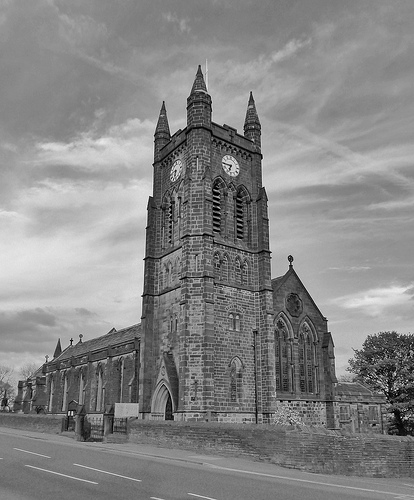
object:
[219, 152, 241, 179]
clock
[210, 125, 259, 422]
wall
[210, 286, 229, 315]
bricks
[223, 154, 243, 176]
6:45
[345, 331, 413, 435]
tree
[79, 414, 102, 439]
gate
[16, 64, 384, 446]
building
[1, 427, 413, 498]
road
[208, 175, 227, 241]
window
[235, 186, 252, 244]
window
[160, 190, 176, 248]
window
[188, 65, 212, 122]
spire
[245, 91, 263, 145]
spire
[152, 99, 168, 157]
spire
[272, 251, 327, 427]
building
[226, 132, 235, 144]
cross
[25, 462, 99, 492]
stripe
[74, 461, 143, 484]
stripe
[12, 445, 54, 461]
stripe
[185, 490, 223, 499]
stripe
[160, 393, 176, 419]
door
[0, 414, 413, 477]
brick wall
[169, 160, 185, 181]
clock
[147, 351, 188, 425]
arch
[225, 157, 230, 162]
roman numerals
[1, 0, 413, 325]
sky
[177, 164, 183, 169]
roman numerals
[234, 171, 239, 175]
roman numerals